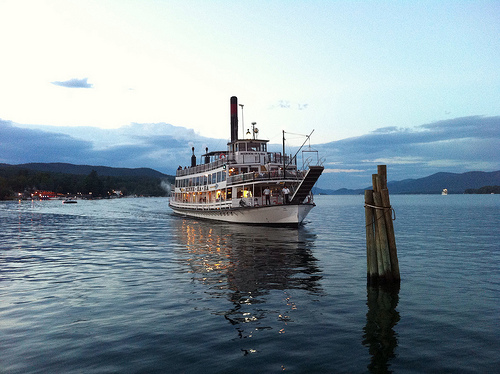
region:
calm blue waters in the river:
[19, 249, 131, 304]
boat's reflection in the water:
[161, 228, 231, 265]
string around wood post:
[349, 196, 413, 228]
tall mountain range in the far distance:
[413, 161, 470, 198]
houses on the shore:
[16, 179, 103, 203]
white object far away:
[431, 183, 458, 205]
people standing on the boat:
[258, 180, 298, 207]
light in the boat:
[200, 178, 268, 207]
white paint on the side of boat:
[221, 210, 297, 225]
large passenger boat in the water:
[151, 93, 333, 249]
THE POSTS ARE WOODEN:
[358, 155, 414, 302]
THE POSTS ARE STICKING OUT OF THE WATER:
[338, 157, 407, 294]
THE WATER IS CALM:
[15, 178, 497, 372]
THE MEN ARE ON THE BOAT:
[258, 178, 293, 216]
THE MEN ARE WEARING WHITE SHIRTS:
[259, 183, 293, 208]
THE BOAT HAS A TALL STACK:
[221, 90, 249, 152]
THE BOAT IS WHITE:
[150, 90, 331, 247]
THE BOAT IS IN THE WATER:
[145, 82, 346, 252]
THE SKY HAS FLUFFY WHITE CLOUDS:
[0, 52, 497, 205]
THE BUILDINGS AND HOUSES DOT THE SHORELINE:
[6, 175, 133, 229]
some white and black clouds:
[0, 120, 211, 163]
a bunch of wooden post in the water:
[361, 160, 399, 279]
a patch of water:
[4, 223, 353, 371]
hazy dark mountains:
[374, 167, 499, 195]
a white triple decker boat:
[164, 93, 333, 229]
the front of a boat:
[251, 161, 331, 226]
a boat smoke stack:
[226, 91, 241, 141]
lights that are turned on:
[16, 190, 100, 196]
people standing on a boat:
[259, 184, 289, 206]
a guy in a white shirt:
[261, 184, 273, 206]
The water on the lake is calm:
[17, 232, 357, 363]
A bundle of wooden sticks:
[355, 158, 403, 281]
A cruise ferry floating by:
[165, 89, 331, 243]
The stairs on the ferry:
[288, 158, 328, 215]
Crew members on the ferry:
[263, 185, 296, 207]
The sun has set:
[66, 24, 451, 92]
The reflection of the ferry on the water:
[162, 207, 313, 348]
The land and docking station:
[13, 182, 144, 202]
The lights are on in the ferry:
[237, 182, 252, 197]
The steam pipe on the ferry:
[227, 90, 243, 145]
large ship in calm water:
[15, 25, 465, 343]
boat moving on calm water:
[7, 13, 492, 364]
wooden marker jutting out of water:
[355, 155, 410, 292]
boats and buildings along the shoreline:
[9, 177, 134, 212]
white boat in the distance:
[440, 185, 451, 195]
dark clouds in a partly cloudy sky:
[9, 99, 172, 165]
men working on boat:
[260, 185, 291, 205]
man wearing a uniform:
[281, 185, 289, 202]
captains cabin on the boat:
[226, 137, 267, 167]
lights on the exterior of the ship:
[168, 189, 250, 206]